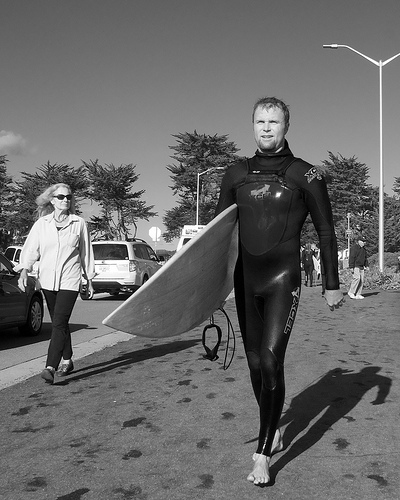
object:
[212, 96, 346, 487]
man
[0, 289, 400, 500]
ground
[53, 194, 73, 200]
sunglasses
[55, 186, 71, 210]
face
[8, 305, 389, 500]
footprints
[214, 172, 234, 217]
man's arm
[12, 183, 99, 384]
woman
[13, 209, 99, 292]
shirt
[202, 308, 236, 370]
ankle strap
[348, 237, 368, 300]
man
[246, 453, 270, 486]
feet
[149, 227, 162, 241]
sign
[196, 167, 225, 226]
street lamp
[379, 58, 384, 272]
pole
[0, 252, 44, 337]
car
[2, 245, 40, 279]
car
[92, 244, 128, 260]
window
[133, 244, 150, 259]
window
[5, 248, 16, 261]
window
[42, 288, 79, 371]
pants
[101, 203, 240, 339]
surfboard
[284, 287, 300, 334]
logo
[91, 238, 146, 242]
roof rack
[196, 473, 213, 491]
spot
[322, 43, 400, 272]
lamp post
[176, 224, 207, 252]
van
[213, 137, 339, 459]
wetsuit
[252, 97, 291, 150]
head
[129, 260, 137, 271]
tail light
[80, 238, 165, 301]
car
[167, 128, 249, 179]
leaves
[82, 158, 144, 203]
leaves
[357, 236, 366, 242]
cap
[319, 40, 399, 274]
light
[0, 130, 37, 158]
cloud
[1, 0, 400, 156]
sky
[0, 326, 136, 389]
curb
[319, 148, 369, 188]
leaves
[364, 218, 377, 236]
leaves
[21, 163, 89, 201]
leaves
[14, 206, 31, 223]
leaves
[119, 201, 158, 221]
leaves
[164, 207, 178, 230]
leaves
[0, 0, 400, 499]
scene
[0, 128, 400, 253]
trees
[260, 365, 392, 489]
shadow